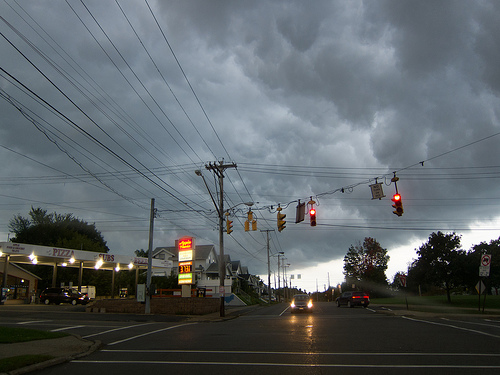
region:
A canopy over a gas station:
[0, 237, 174, 272]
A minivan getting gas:
[36, 282, 91, 307]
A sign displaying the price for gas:
[175, 259, 195, 280]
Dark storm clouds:
[1, 1, 496, 219]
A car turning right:
[331, 284, 373, 311]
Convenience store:
[0, 256, 42, 305]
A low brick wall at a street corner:
[81, 294, 228, 311]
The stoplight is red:
[304, 166, 413, 230]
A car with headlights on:
[286, 289, 317, 314]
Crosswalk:
[71, 350, 497, 367]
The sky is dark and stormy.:
[1, 0, 498, 290]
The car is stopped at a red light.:
[287, 291, 314, 315]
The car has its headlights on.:
[288, 290, 316, 317]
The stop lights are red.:
[306, 189, 405, 226]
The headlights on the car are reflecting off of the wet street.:
[286, 310, 318, 373]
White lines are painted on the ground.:
[15, 302, 497, 373]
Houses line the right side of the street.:
[148, 239, 276, 302]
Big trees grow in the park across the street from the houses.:
[340, 225, 499, 312]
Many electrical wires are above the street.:
[1, 0, 499, 288]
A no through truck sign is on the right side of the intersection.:
[476, 250, 492, 279]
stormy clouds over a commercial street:
[46, 75, 462, 335]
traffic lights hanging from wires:
[195, 135, 490, 240]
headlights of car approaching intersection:
[266, 271, 321, 331]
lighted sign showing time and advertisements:
[165, 221, 220, 301]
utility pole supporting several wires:
[140, 60, 275, 280]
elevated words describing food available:
[10, 231, 175, 326]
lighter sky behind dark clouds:
[242, 200, 493, 305]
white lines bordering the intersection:
[25, 295, 485, 367]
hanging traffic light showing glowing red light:
[380, 160, 413, 225]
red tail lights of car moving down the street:
[321, 270, 376, 315]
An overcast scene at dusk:
[43, 27, 467, 342]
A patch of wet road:
[167, 324, 392, 364]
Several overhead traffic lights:
[216, 176, 415, 238]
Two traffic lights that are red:
[296, 188, 421, 230]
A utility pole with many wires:
[188, 143, 255, 327]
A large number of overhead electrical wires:
[12, 13, 252, 232]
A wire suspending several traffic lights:
[224, 128, 492, 248]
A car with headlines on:
[282, 291, 315, 316]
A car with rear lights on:
[336, 286, 372, 310]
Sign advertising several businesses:
[172, 231, 198, 303]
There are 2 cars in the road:
[262, 272, 418, 337]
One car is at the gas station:
[30, 253, 114, 324]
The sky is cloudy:
[91, 176, 461, 304]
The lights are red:
[257, 190, 432, 256]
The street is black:
[81, 315, 423, 371]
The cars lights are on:
[275, 283, 427, 345]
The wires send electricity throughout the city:
[83, 147, 437, 249]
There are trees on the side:
[299, 229, 490, 324]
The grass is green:
[378, 277, 474, 335]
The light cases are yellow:
[198, 192, 315, 264]